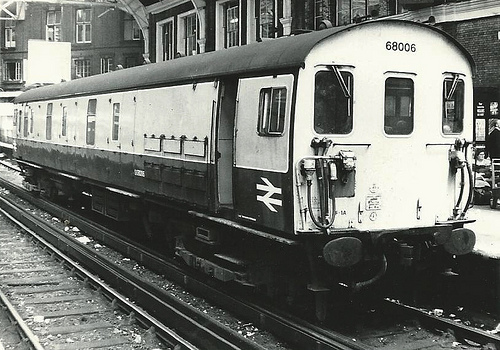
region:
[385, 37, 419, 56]
black number on a white surface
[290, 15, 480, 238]
backside of a train car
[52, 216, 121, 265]
litter between rail way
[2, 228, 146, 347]
dirty littered rail way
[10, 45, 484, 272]
lone black and white passenger car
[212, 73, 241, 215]
open door on side of train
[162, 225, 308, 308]
wheels under train car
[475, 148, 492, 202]
woman sitting in chair on platform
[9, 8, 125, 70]
old brick building with white windows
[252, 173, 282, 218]
white pattern paint on train car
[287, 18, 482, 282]
The front of a train car.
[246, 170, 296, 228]
Arrows on the side of a train.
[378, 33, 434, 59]
a serial number on a train car.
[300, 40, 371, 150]
A window on a train car.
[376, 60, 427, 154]
A small window on a train car.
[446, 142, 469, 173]
a headlight on a train car.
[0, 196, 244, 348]
train tracks near a train.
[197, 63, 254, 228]
a door on the side of a train.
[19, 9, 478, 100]
the top of a train car.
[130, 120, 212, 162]
the side of a train.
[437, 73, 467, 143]
window on a train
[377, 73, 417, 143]
window on a train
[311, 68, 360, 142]
window on a train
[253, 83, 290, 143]
window on a train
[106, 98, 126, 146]
window on a train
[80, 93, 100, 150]
window on a train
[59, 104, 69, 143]
window on a train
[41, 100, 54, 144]
window on a train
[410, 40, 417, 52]
number on a train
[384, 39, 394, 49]
number on a train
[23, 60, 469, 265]
A train on the track.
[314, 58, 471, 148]
Three windows in the front of the train.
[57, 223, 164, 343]
Gravel and rocks on the tracks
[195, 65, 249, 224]
A door opening on the train.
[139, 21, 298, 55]
Windows on the building.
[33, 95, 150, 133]
Windows on the side of the train.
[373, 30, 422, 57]
A number in front of the train.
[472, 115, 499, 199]
People on the walkway.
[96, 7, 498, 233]
A building on the side of the train.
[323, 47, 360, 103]
Windshield wipers on the window of the train.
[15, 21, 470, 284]
white train on train tracks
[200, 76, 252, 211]
open door on train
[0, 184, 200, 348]
train tracks not being used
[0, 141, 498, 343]
tracks white train is on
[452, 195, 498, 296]
platform next to train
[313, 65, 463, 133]
front windows of train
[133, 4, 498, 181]
train station behind train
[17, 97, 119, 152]
windows on side of train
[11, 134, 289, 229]
dark strip running down side of train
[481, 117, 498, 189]
person standing on platform